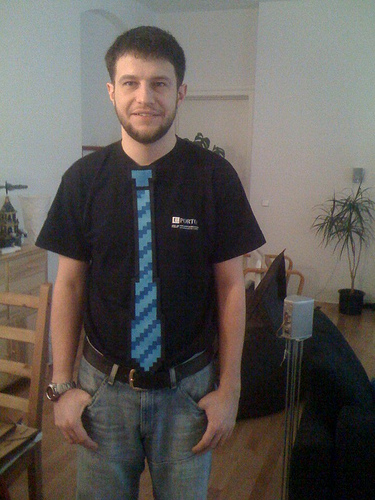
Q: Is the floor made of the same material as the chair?
A: Yes, both the floor and the chair are made of wood.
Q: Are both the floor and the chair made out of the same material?
A: Yes, both the floor and the chair are made of wood.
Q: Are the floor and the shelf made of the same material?
A: Yes, both the floor and the shelf are made of wood.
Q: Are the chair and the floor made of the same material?
A: Yes, both the chair and the floor are made of wood.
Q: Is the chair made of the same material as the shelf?
A: Yes, both the chair and the shelf are made of wood.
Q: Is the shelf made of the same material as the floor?
A: Yes, both the shelf and the floor are made of wood.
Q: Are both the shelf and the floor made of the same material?
A: Yes, both the shelf and the floor are made of wood.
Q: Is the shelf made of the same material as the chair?
A: Yes, both the shelf and the chair are made of wood.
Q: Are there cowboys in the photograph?
A: No, there are no cowboys.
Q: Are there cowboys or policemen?
A: No, there are no cowboys or policemen.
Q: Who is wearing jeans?
A: The man is wearing jeans.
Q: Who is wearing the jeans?
A: The man is wearing jeans.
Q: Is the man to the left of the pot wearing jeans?
A: Yes, the man is wearing jeans.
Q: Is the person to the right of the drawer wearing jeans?
A: Yes, the man is wearing jeans.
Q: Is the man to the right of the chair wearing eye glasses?
A: No, the man is wearing jeans.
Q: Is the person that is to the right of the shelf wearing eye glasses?
A: No, the man is wearing jeans.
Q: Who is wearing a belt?
A: The man is wearing a belt.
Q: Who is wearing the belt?
A: The man is wearing a belt.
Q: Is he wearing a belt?
A: Yes, the man is wearing a belt.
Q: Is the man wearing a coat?
A: No, the man is wearing a belt.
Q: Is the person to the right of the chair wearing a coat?
A: No, the man is wearing a belt.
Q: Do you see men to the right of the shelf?
A: Yes, there is a man to the right of the shelf.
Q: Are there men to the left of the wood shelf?
A: No, the man is to the right of the shelf.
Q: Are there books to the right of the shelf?
A: No, there is a man to the right of the shelf.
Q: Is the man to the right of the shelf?
A: Yes, the man is to the right of the shelf.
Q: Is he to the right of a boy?
A: No, the man is to the right of the shelf.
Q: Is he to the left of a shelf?
A: No, the man is to the right of a shelf.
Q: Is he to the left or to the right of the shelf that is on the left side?
A: The man is to the right of the shelf.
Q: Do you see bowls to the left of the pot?
A: No, there is a man to the left of the pot.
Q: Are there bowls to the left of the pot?
A: No, there is a man to the left of the pot.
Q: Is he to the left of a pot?
A: Yes, the man is to the left of a pot.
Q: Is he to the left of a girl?
A: No, the man is to the left of a pot.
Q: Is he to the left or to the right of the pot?
A: The man is to the left of the pot.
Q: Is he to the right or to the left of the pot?
A: The man is to the left of the pot.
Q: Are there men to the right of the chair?
A: Yes, there is a man to the right of the chair.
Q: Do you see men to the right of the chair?
A: Yes, there is a man to the right of the chair.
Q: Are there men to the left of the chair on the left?
A: No, the man is to the right of the chair.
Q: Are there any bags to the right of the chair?
A: No, there is a man to the right of the chair.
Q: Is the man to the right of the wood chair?
A: Yes, the man is to the right of the chair.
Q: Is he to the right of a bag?
A: No, the man is to the right of the chair.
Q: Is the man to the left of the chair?
A: No, the man is to the right of the chair.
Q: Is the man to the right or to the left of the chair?
A: The man is to the right of the chair.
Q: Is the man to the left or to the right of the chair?
A: The man is to the right of the chair.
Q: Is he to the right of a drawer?
A: Yes, the man is to the right of a drawer.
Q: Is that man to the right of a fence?
A: No, the man is to the right of a drawer.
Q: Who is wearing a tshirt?
A: The man is wearing a tshirt.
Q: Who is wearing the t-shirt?
A: The man is wearing a tshirt.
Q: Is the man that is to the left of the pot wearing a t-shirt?
A: Yes, the man is wearing a t-shirt.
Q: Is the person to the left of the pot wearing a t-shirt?
A: Yes, the man is wearing a t-shirt.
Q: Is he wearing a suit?
A: No, the man is wearing a t-shirt.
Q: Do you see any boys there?
A: No, there are no boys.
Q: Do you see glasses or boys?
A: No, there are no boys or glasses.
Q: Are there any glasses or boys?
A: No, there are no boys or glasses.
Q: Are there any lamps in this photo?
A: No, there are no lamps.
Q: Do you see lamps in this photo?
A: No, there are no lamps.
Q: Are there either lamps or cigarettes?
A: No, there are no lamps or cigarettes.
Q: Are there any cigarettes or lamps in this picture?
A: No, there are no lamps or cigarettes.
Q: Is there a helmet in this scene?
A: No, there are no helmets.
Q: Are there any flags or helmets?
A: No, there are no helmets or flags.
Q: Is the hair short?
A: Yes, the hair is short.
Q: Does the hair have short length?
A: Yes, the hair is short.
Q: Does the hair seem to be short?
A: Yes, the hair is short.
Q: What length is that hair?
A: The hair is short.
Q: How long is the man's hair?
A: The hair is short.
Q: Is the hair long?
A: No, the hair is short.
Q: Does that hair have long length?
A: No, the hair is short.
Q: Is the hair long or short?
A: The hair is short.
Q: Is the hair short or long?
A: The hair is short.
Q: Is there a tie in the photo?
A: Yes, there is a tie.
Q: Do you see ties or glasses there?
A: Yes, there is a tie.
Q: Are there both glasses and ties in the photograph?
A: No, there is a tie but no glasses.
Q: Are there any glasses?
A: No, there are no glasses.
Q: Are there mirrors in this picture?
A: No, there are no mirrors.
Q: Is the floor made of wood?
A: Yes, the floor is made of wood.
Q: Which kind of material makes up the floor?
A: The floor is made of wood.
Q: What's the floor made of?
A: The floor is made of wood.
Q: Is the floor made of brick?
A: No, the floor is made of wood.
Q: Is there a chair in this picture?
A: Yes, there is a chair.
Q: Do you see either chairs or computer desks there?
A: Yes, there is a chair.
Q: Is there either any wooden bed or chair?
A: Yes, there is a wood chair.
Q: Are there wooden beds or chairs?
A: Yes, there is a wood chair.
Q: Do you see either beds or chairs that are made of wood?
A: Yes, the chair is made of wood.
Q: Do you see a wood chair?
A: Yes, there is a chair that is made of wood.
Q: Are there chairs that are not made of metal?
A: Yes, there is a chair that is made of wood.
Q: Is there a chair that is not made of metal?
A: Yes, there is a chair that is made of wood.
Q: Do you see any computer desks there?
A: No, there are no computer desks.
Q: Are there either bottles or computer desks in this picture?
A: No, there are no computer desks or bottles.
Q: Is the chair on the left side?
A: Yes, the chair is on the left of the image.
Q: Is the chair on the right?
A: No, the chair is on the left of the image.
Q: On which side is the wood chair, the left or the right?
A: The chair is on the left of the image.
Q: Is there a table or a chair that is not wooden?
A: No, there is a chair but it is wooden.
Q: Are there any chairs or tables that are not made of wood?
A: No, there is a chair but it is made of wood.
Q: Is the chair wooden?
A: Yes, the chair is wooden.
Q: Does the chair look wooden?
A: Yes, the chair is wooden.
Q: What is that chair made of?
A: The chair is made of wood.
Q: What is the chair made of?
A: The chair is made of wood.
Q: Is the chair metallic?
A: No, the chair is wooden.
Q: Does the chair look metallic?
A: No, the chair is wooden.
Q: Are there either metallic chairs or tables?
A: No, there is a chair but it is wooden.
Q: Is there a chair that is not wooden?
A: No, there is a chair but it is wooden.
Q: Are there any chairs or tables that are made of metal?
A: No, there is a chair but it is made of wood.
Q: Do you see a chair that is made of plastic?
A: No, there is a chair but it is made of wood.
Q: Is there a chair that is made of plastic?
A: No, there is a chair but it is made of wood.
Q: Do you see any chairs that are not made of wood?
A: No, there is a chair but it is made of wood.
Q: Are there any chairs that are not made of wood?
A: No, there is a chair but it is made of wood.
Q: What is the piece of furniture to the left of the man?
A: The piece of furniture is a chair.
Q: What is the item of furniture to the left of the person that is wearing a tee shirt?
A: The piece of furniture is a chair.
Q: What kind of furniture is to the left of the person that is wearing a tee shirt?
A: The piece of furniture is a chair.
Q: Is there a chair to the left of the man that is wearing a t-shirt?
A: Yes, there is a chair to the left of the man.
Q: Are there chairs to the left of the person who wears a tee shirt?
A: Yes, there is a chair to the left of the man.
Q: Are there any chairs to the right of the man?
A: No, the chair is to the left of the man.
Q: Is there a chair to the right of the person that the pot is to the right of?
A: No, the chair is to the left of the man.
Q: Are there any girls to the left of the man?
A: No, there is a chair to the left of the man.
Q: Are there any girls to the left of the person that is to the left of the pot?
A: No, there is a chair to the left of the man.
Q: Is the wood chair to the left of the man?
A: Yes, the chair is to the left of the man.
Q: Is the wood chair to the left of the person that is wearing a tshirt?
A: Yes, the chair is to the left of the man.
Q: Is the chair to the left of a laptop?
A: No, the chair is to the left of the man.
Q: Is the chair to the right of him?
A: No, the chair is to the left of a man.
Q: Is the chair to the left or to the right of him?
A: The chair is to the left of the man.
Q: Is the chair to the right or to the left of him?
A: The chair is to the left of the man.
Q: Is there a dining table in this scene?
A: No, there are no dining tables.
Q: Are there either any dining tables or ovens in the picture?
A: No, there are no dining tables or ovens.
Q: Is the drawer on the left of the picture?
A: Yes, the drawer is on the left of the image.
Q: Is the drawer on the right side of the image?
A: No, the drawer is on the left of the image.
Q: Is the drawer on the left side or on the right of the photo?
A: The drawer is on the left of the image.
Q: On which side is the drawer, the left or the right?
A: The drawer is on the left of the image.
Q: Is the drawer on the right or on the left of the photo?
A: The drawer is on the left of the image.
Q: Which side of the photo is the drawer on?
A: The drawer is on the left of the image.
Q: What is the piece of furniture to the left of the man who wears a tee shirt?
A: The piece of furniture is a drawer.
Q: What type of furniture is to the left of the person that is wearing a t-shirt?
A: The piece of furniture is a drawer.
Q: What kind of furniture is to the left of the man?
A: The piece of furniture is a drawer.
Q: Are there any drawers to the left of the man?
A: Yes, there is a drawer to the left of the man.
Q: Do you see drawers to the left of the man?
A: Yes, there is a drawer to the left of the man.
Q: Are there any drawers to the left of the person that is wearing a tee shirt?
A: Yes, there is a drawer to the left of the man.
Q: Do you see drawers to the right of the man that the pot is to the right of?
A: No, the drawer is to the left of the man.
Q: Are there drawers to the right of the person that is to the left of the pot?
A: No, the drawer is to the left of the man.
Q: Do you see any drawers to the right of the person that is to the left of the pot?
A: No, the drawer is to the left of the man.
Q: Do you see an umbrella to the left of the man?
A: No, there is a drawer to the left of the man.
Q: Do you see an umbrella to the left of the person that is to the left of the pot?
A: No, there is a drawer to the left of the man.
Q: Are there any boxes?
A: No, there are no boxes.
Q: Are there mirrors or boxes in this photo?
A: No, there are no boxes or mirrors.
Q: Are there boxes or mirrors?
A: No, there are no boxes or mirrors.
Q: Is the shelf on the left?
A: Yes, the shelf is on the left of the image.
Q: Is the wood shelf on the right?
A: No, the shelf is on the left of the image.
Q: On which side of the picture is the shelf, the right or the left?
A: The shelf is on the left of the image.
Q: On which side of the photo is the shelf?
A: The shelf is on the left of the image.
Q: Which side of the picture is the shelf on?
A: The shelf is on the left of the image.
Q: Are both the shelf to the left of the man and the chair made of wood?
A: Yes, both the shelf and the chair are made of wood.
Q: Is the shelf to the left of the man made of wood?
A: Yes, the shelf is made of wood.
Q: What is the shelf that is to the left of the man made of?
A: The shelf is made of wood.